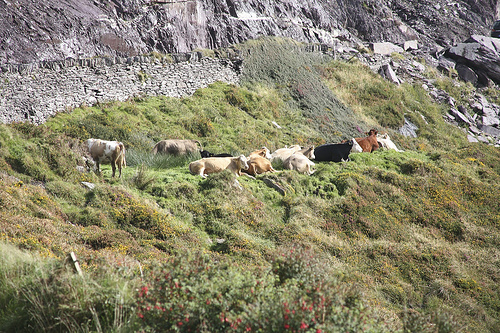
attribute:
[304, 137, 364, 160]
cow — black and white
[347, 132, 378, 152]
cow — brown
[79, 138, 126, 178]
cow — tan and white, eating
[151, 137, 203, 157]
cow — eating, tan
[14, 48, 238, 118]
wall — rock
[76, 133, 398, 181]
cows — several